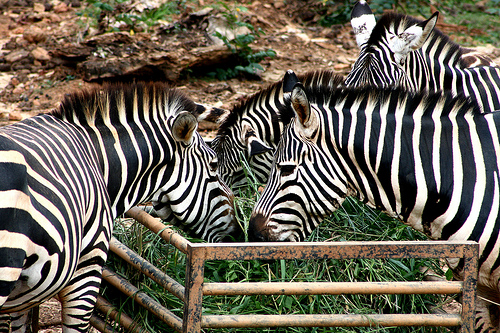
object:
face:
[181, 154, 234, 228]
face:
[272, 134, 322, 240]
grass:
[206, 229, 409, 311]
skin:
[354, 108, 412, 181]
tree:
[50, 2, 266, 79]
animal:
[0, 81, 237, 333]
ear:
[291, 82, 311, 127]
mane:
[231, 69, 476, 117]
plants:
[211, 25, 269, 77]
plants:
[78, 3, 190, 27]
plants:
[303, 0, 492, 36]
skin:
[432, 115, 483, 199]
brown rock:
[52, 32, 288, 82]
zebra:
[345, 11, 500, 115]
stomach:
[11, 255, 74, 310]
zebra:
[249, 76, 499, 330]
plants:
[222, 207, 426, 312]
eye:
[277, 160, 295, 177]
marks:
[463, 274, 478, 306]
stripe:
[340, 96, 363, 195]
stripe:
[369, 92, 379, 171]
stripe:
[380, 92, 400, 211]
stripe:
[397, 88, 424, 228]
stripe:
[442, 109, 481, 238]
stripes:
[0, 125, 76, 292]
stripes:
[361, 45, 480, 95]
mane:
[53, 80, 197, 130]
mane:
[367, 10, 459, 42]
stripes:
[82, 125, 153, 161]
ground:
[1, 1, 361, 141]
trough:
[112, 194, 478, 331]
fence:
[100, 207, 483, 326]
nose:
[231, 211, 245, 226]